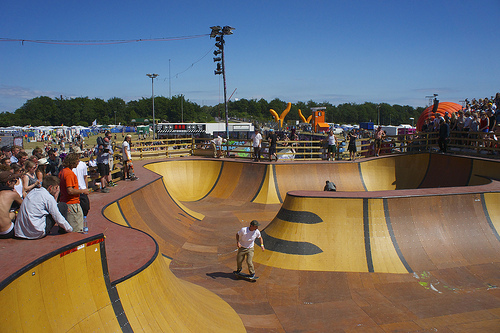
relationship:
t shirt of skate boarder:
[237, 226, 260, 253] [227, 217, 265, 282]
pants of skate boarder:
[235, 245, 255, 275] [230, 218, 267, 279]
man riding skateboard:
[224, 211, 274, 288] [225, 265, 262, 288]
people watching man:
[7, 141, 135, 228] [13, 175, 74, 241]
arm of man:
[256, 232, 263, 246] [231, 219, 266, 281]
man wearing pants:
[233, 219, 267, 278] [236, 245, 258, 275]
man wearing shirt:
[54, 148, 93, 227] [52, 167, 84, 204]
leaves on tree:
[113, 104, 136, 114] [383, 104, 396, 126]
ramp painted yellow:
[4, 152, 499, 332] [331, 227, 351, 264]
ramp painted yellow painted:
[4, 152, 499, 332] [323, 203, 386, 262]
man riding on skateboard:
[233, 219, 267, 278] [233, 270, 260, 284]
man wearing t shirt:
[233, 219, 267, 278] [237, 226, 260, 250]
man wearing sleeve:
[233, 219, 267, 278] [234, 227, 246, 236]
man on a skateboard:
[233, 219, 267, 278] [234, 271, 256, 280]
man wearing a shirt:
[56, 153, 91, 233] [56, 167, 78, 204]